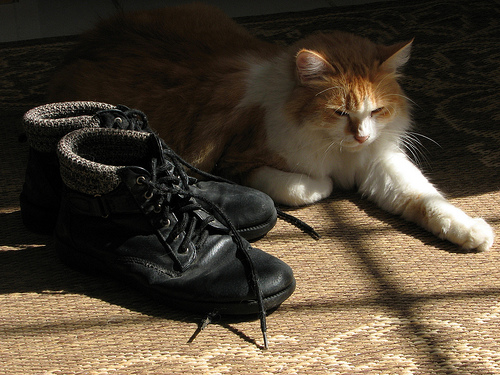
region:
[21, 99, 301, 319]
Shoes on the floor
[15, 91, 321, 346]
Black shoes on the floor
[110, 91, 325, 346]
Laces on shoes are untied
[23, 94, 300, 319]
Laces on black shoes are untied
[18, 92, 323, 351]
Shoes are on the ground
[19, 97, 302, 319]
Black shoes are on the ground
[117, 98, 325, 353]
Shoes have laces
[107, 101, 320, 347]
Shoes have black laces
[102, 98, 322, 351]
Black shoes have laces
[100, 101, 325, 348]
Black shoes have black laces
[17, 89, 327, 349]
a pair of black shoes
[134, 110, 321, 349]
black shoe strings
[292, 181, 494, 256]
paws of a cat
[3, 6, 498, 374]
carpet on floor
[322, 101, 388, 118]
the ears of cat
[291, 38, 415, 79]
the pointy ears of cat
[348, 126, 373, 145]
the nose of cat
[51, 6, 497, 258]
a golden brown and white cat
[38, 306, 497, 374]
the imprint on rug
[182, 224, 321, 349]
the tips of strings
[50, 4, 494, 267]
orange and white cat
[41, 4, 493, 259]
long hair cat laying on floor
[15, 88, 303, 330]
pair of black shoes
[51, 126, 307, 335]
untied black boot for right foot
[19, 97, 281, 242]
black boot for left foot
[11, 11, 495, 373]
tightly woven area rug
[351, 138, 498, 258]
outstretched front cat paw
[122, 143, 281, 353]
untied black shoe lace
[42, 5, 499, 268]
orange and white cat relaxing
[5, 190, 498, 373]
shadows cast on the floor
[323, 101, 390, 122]
tired cat's closing eyes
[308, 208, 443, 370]
shadow of window pane molding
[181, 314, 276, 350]
black shoe lace ends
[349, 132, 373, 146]
cat's litle pink nose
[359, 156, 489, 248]
cat's stretched out leg and paw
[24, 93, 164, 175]
black and white boot cuffs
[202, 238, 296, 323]
toe of black boot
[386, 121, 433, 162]
cat's whiskers illuminated by the sun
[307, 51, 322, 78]
cat's long white ear hair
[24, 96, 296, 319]
pair of boots next to cat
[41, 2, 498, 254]
A TAN AND WHITE CAT ON THE CARPET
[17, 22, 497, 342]
A CAT NEXT TO A PAIR OF BLACK BOOTIES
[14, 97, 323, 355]
A PAIR OF BLACK BOOTIES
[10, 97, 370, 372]
A PAIR OF BLACK SHOES ON THE CARPET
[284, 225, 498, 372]
A TAN CARPET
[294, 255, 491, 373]
SUN SHINING ON THE CARPET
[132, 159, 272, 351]
BLACK SHOE LACES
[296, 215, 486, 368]
A SHADOW ON THE CARPET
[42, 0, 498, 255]
THE SUN SHINING ON THE CAT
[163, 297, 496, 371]
A WHITE DESIGN ON THE CARPET